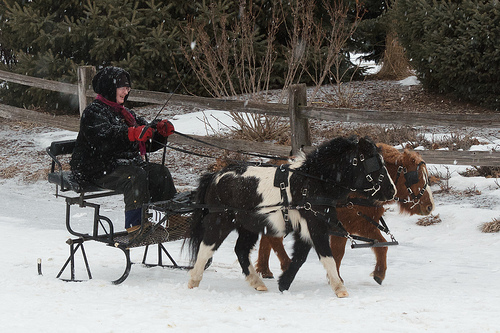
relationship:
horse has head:
[384, 134, 437, 219] [378, 148, 442, 211]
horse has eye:
[256, 139, 436, 277] [343, 148, 396, 185]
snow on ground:
[414, 242, 481, 291] [94, 281, 459, 329]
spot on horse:
[254, 176, 309, 214] [194, 126, 382, 299]